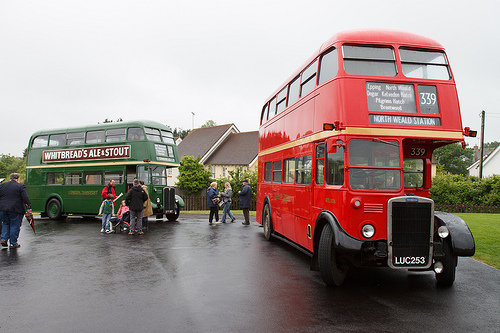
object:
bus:
[255, 31, 476, 289]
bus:
[22, 121, 187, 222]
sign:
[366, 78, 414, 112]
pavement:
[5, 212, 498, 333]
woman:
[207, 181, 222, 225]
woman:
[221, 181, 236, 223]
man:
[238, 180, 253, 225]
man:
[125, 178, 148, 235]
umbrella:
[22, 207, 38, 236]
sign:
[41, 145, 132, 164]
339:
[419, 92, 436, 106]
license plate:
[392, 252, 426, 267]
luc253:
[394, 256, 427, 265]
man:
[100, 179, 117, 225]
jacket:
[102, 187, 117, 202]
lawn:
[474, 211, 499, 263]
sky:
[0, 1, 497, 150]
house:
[171, 123, 258, 188]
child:
[98, 193, 115, 232]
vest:
[102, 200, 112, 213]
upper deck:
[255, 31, 461, 136]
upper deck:
[22, 121, 180, 164]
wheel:
[317, 220, 342, 288]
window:
[343, 42, 398, 79]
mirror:
[327, 139, 337, 153]